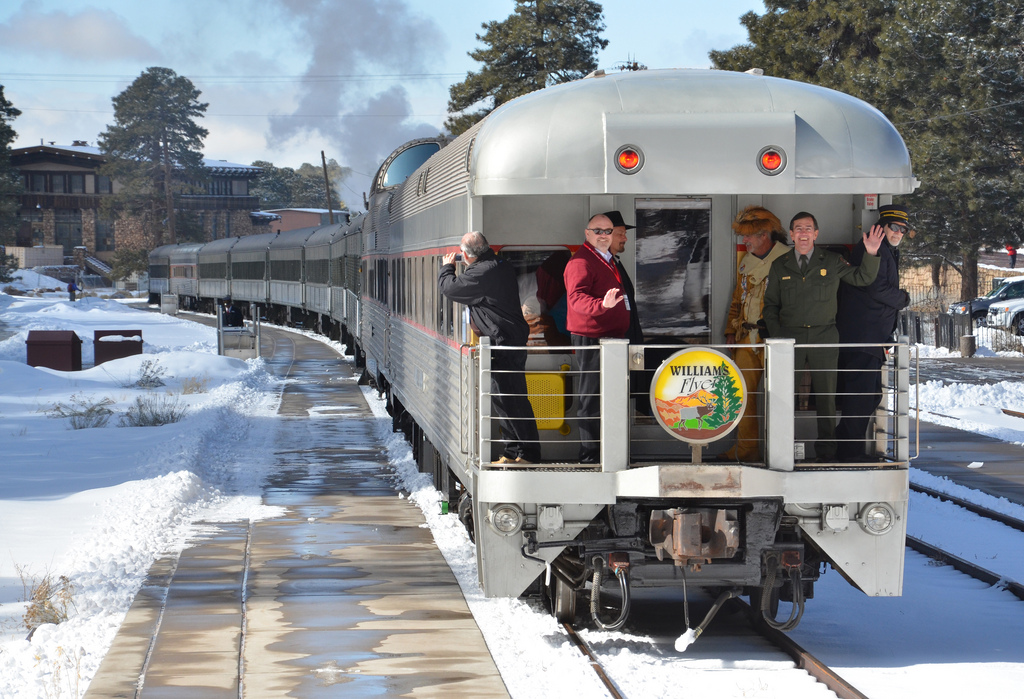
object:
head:
[584, 214, 612, 252]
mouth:
[597, 244, 610, 250]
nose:
[599, 231, 607, 239]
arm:
[562, 256, 611, 321]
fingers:
[603, 288, 623, 308]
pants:
[572, 336, 621, 464]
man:
[564, 213, 632, 462]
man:
[603, 211, 650, 417]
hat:
[602, 211, 637, 230]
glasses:
[588, 228, 615, 236]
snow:
[463, 544, 1022, 699]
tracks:
[566, 594, 857, 694]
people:
[438, 205, 911, 463]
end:
[463, 68, 915, 654]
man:
[762, 212, 885, 463]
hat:
[877, 204, 910, 224]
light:
[614, 143, 646, 175]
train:
[150, 71, 906, 636]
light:
[755, 145, 787, 177]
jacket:
[762, 245, 882, 339]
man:
[833, 205, 912, 458]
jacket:
[840, 236, 912, 363]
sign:
[649, 346, 748, 444]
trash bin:
[25, 330, 83, 372]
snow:
[0, 268, 1024, 699]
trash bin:
[92, 329, 143, 366]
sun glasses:
[586, 228, 614, 236]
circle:
[649, 346, 748, 444]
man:
[722, 205, 914, 465]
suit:
[759, 245, 883, 341]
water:
[120, 473, 385, 668]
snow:
[372, 377, 1024, 699]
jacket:
[564, 240, 632, 338]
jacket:
[436, 249, 531, 346]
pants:
[490, 345, 540, 470]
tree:
[99, 67, 208, 242]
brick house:
[0, 138, 347, 342]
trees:
[704, 0, 1024, 333]